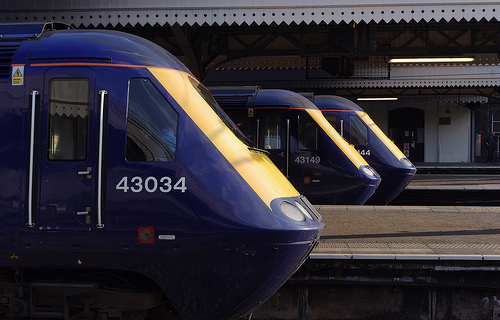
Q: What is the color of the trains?
A: Blue and yellow.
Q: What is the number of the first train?
A: 43034.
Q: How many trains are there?
A: 3.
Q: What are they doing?
A: Parked.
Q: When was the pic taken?
A: During the day.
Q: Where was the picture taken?
A: Train station.